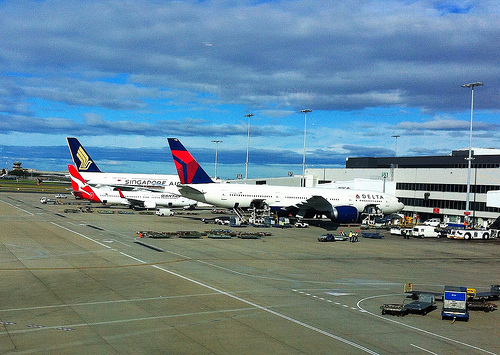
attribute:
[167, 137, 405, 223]
plane — white, red, blue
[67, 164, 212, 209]
plane — white, red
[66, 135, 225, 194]
plane — white, blue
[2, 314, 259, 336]
line — white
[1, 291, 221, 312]
line — white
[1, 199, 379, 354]
line — white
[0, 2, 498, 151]
sky — cloudy, blue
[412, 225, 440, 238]
van — white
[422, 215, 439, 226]
van — white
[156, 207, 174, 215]
van — white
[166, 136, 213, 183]
tail — red, blue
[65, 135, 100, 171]
tail — yellow, blue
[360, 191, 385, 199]
branding — delta airlines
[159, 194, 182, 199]
branding — qantas airlines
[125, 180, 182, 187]
branding — singapore airlines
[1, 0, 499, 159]
clouds — gray, white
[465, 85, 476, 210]
pole — metal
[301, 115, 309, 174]
pole — metal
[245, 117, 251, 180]
pole — metal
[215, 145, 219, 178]
pole — metal